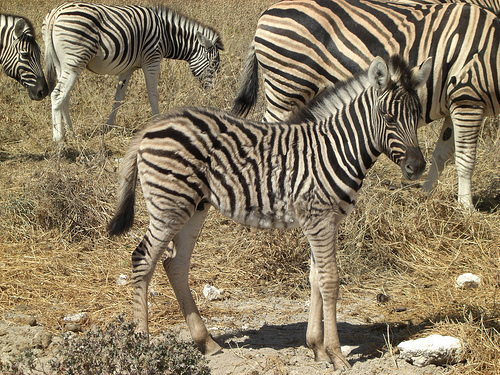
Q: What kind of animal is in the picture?
A: Zebras.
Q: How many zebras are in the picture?
A: Four.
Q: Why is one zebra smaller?
A: It is a baby.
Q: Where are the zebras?
A: Standing in short grass.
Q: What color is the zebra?
A: Black and white.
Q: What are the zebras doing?
A: Standing.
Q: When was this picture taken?
A: Daytime.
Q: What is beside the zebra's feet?
A: Some rocks.